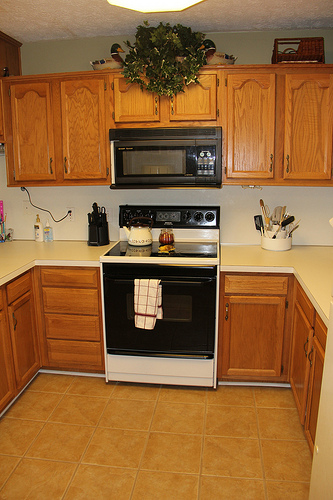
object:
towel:
[132, 278, 165, 333]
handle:
[113, 278, 212, 285]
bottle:
[43, 219, 53, 241]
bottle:
[33, 213, 42, 242]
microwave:
[108, 125, 224, 190]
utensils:
[253, 215, 262, 229]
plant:
[120, 24, 208, 99]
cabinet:
[0, 65, 107, 189]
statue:
[199, 39, 237, 65]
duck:
[200, 39, 237, 63]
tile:
[202, 403, 259, 441]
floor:
[2, 410, 312, 499]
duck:
[88, 43, 130, 69]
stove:
[99, 200, 219, 380]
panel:
[117, 205, 218, 231]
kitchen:
[2, 2, 331, 497]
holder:
[258, 222, 290, 251]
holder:
[88, 213, 109, 247]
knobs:
[165, 214, 168, 218]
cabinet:
[222, 265, 283, 388]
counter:
[0, 238, 330, 324]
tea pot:
[122, 223, 153, 247]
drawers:
[41, 287, 102, 315]